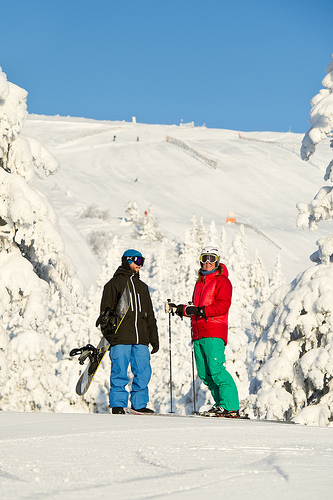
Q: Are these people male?
A: No, they are both male and female.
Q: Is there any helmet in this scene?
A: Yes, there is a helmet.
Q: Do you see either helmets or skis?
A: Yes, there is a helmet.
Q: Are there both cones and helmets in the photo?
A: No, there is a helmet but no cones.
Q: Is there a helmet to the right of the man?
A: Yes, there is a helmet to the right of the man.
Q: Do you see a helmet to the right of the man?
A: Yes, there is a helmet to the right of the man.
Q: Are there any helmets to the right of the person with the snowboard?
A: Yes, there is a helmet to the right of the man.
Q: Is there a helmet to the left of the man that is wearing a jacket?
A: No, the helmet is to the right of the man.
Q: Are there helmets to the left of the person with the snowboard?
A: No, the helmet is to the right of the man.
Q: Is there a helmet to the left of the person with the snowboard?
A: No, the helmet is to the right of the man.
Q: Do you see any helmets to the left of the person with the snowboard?
A: No, the helmet is to the right of the man.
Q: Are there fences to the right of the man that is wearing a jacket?
A: No, there is a helmet to the right of the man.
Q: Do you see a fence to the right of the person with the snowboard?
A: No, there is a helmet to the right of the man.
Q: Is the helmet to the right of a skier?
A: No, the helmet is to the right of the man.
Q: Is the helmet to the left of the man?
A: No, the helmet is to the right of the man.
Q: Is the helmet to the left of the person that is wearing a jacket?
A: No, the helmet is to the right of the man.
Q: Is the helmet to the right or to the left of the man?
A: The helmet is to the right of the man.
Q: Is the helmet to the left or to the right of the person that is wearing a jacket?
A: The helmet is to the right of the man.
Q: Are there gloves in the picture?
A: Yes, there are gloves.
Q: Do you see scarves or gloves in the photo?
A: Yes, there are gloves.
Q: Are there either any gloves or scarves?
A: Yes, there are gloves.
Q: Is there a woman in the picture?
A: Yes, there is a woman.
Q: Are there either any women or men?
A: Yes, there is a woman.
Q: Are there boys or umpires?
A: No, there are no boys or umpires.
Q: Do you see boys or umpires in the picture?
A: No, there are no boys or umpires.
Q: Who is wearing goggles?
A: The woman is wearing goggles.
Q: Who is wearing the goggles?
A: The woman is wearing goggles.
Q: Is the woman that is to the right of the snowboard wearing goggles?
A: Yes, the woman is wearing goggles.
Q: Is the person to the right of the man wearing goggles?
A: Yes, the woman is wearing goggles.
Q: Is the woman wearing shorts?
A: No, the woman is wearing goggles.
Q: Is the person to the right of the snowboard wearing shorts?
A: No, the woman is wearing goggles.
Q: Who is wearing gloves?
A: The woman is wearing gloves.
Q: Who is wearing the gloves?
A: The woman is wearing gloves.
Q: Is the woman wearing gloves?
A: Yes, the woman is wearing gloves.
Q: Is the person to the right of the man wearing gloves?
A: Yes, the woman is wearing gloves.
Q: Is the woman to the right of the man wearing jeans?
A: No, the woman is wearing gloves.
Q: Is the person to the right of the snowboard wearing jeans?
A: No, the woman is wearing gloves.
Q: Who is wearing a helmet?
A: The woman is wearing a helmet.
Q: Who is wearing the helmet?
A: The woman is wearing a helmet.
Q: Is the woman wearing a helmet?
A: Yes, the woman is wearing a helmet.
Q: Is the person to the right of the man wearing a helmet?
A: Yes, the woman is wearing a helmet.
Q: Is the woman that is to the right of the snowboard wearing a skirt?
A: No, the woman is wearing a helmet.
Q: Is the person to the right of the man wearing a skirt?
A: No, the woman is wearing a helmet.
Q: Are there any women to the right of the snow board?
A: Yes, there is a woman to the right of the snow board.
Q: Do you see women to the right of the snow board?
A: Yes, there is a woman to the right of the snow board.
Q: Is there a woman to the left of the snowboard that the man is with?
A: No, the woman is to the right of the snowboard.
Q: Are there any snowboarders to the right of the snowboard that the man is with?
A: No, there is a woman to the right of the snow board.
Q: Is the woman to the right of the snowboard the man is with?
A: Yes, the woman is to the right of the snowboard.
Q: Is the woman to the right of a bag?
A: No, the woman is to the right of the snowboard.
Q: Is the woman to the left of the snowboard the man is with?
A: No, the woman is to the right of the snowboard.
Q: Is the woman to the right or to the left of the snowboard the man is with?
A: The woman is to the right of the snowboard.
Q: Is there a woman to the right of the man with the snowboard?
A: Yes, there is a woman to the right of the man.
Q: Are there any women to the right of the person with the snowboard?
A: Yes, there is a woman to the right of the man.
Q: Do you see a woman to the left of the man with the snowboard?
A: No, the woman is to the right of the man.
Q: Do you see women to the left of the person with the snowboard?
A: No, the woman is to the right of the man.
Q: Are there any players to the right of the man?
A: No, there is a woman to the right of the man.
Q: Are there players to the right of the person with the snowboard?
A: No, there is a woman to the right of the man.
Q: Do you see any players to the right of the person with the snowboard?
A: No, there is a woman to the right of the man.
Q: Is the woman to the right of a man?
A: Yes, the woman is to the right of a man.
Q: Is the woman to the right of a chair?
A: No, the woman is to the right of a man.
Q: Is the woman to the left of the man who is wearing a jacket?
A: No, the woman is to the right of the man.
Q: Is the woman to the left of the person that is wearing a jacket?
A: No, the woman is to the right of the man.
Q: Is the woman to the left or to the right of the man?
A: The woman is to the right of the man.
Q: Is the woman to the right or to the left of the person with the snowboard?
A: The woman is to the right of the man.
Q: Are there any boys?
A: No, there are no boys.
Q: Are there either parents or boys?
A: No, there are no boys or parents.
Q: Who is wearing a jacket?
A: The man is wearing a jacket.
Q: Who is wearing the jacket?
A: The man is wearing a jacket.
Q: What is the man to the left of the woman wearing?
A: The man is wearing a jacket.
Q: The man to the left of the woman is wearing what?
A: The man is wearing a jacket.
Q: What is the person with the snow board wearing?
A: The man is wearing a jacket.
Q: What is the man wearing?
A: The man is wearing a jacket.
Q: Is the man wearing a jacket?
A: Yes, the man is wearing a jacket.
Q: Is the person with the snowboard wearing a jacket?
A: Yes, the man is wearing a jacket.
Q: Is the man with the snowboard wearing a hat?
A: No, the man is wearing a jacket.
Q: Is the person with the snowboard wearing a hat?
A: No, the man is wearing a jacket.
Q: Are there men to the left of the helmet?
A: Yes, there is a man to the left of the helmet.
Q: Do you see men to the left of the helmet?
A: Yes, there is a man to the left of the helmet.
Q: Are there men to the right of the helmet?
A: No, the man is to the left of the helmet.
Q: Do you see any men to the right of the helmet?
A: No, the man is to the left of the helmet.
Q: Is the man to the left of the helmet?
A: Yes, the man is to the left of the helmet.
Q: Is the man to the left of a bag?
A: No, the man is to the left of the helmet.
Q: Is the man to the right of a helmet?
A: No, the man is to the left of a helmet.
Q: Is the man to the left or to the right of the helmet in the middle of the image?
A: The man is to the left of the helmet.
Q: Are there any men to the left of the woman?
A: Yes, there is a man to the left of the woman.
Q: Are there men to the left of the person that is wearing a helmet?
A: Yes, there is a man to the left of the woman.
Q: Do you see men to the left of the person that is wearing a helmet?
A: Yes, there is a man to the left of the woman.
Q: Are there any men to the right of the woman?
A: No, the man is to the left of the woman.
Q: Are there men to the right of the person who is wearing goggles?
A: No, the man is to the left of the woman.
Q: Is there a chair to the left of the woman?
A: No, there is a man to the left of the woman.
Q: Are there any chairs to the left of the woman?
A: No, there is a man to the left of the woman.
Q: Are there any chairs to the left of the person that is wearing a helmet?
A: No, there is a man to the left of the woman.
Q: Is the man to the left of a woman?
A: Yes, the man is to the left of a woman.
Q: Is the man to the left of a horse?
A: No, the man is to the left of a woman.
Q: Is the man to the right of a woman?
A: No, the man is to the left of a woman.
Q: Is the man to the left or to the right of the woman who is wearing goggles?
A: The man is to the left of the woman.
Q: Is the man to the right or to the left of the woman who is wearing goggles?
A: The man is to the left of the woman.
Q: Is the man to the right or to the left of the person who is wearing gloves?
A: The man is to the left of the woman.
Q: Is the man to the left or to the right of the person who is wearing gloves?
A: The man is to the left of the woman.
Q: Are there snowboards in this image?
A: Yes, there is a snowboard.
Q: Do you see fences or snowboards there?
A: Yes, there is a snowboard.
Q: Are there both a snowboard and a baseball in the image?
A: No, there is a snowboard but no baseballs.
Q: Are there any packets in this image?
A: No, there are no packets.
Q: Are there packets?
A: No, there are no packets.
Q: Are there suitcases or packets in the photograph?
A: No, there are no packets or suitcases.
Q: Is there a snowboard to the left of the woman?
A: Yes, there is a snowboard to the left of the woman.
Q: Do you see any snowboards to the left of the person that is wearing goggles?
A: Yes, there is a snowboard to the left of the woman.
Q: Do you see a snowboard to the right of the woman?
A: No, the snowboard is to the left of the woman.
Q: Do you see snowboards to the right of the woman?
A: No, the snowboard is to the left of the woman.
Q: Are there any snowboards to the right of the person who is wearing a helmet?
A: No, the snowboard is to the left of the woman.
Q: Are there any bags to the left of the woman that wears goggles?
A: No, there is a snowboard to the left of the woman.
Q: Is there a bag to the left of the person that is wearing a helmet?
A: No, there is a snowboard to the left of the woman.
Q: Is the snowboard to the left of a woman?
A: Yes, the snowboard is to the left of a woman.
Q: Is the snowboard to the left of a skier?
A: No, the snowboard is to the left of a woman.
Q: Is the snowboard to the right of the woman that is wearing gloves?
A: No, the snowboard is to the left of the woman.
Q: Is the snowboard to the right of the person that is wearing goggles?
A: No, the snowboard is to the left of the woman.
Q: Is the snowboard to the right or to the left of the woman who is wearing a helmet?
A: The snowboard is to the left of the woman.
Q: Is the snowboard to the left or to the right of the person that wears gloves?
A: The snowboard is to the left of the woman.